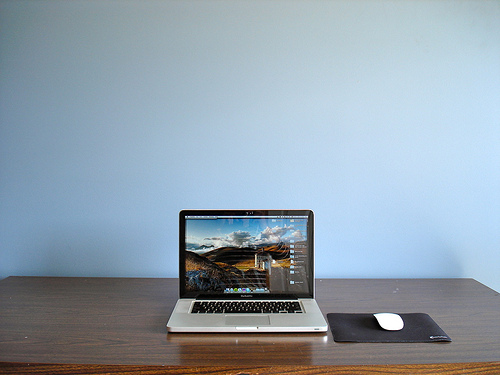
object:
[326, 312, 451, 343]
mouse pad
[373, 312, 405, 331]
computer mouse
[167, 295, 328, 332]
keyboard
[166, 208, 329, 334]
laptop computer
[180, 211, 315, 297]
screen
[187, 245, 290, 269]
mountains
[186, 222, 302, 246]
clouds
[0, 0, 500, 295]
wall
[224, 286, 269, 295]
icons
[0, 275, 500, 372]
desk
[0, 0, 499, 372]
office scene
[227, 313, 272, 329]
touch pad